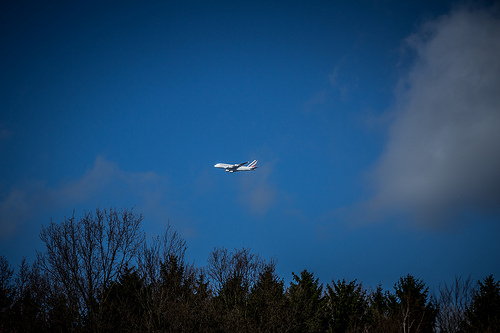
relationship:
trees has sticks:
[14, 206, 494, 326] [32, 214, 142, 330]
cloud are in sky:
[374, 3, 500, 216] [2, 2, 496, 309]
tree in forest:
[35, 211, 141, 331] [2, 205, 497, 333]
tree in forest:
[240, 262, 290, 331] [2, 205, 497, 330]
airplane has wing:
[214, 159, 259, 173] [222, 160, 243, 170]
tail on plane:
[244, 153, 258, 169] [214, 158, 259, 173]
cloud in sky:
[374, 3, 500, 216] [2, 2, 496, 309]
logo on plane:
[247, 158, 258, 168] [212, 154, 260, 171]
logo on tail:
[247, 158, 258, 168] [248, 158, 258, 168]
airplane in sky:
[215, 159, 264, 172] [2, 2, 496, 309]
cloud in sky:
[346, 3, 496, 227] [2, 2, 496, 309]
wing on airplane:
[229, 158, 248, 171] [213, 158, 258, 174]